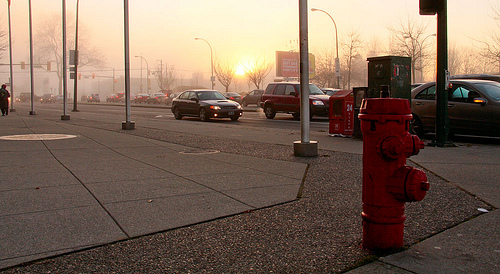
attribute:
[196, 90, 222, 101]
people — driving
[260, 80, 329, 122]
vehicle — red 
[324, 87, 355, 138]
stand — newspaper stand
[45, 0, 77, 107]
pole — gray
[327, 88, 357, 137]
stand — Red, newspaper stand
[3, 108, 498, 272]
sidewalk — Red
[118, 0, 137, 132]
pole — straight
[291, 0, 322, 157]
pole — straight, gray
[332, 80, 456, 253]
hydrant — fire hydrant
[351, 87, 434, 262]
fire hydrant — red 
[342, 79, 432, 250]
hydrant — red 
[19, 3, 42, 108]
pole — gray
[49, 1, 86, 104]
pole — gray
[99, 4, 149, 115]
pole — gray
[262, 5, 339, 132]
pole — gray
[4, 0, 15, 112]
pole — straight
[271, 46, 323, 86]
advertisement — billboard advertisment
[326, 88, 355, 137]
newspaper stand — red 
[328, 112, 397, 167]
ground — newspaper stand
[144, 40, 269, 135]
car — black 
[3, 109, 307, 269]
sidewalk — paved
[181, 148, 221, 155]
cover — manhole cover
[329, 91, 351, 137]
stand — newspaper stand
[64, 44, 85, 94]
laws — traffic